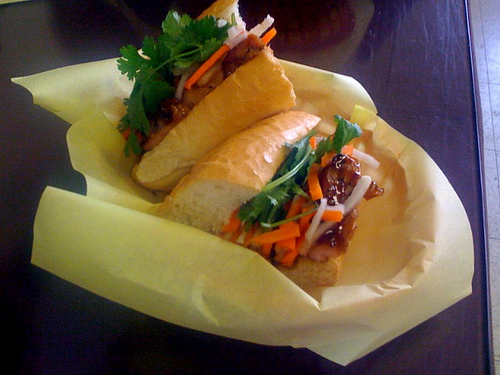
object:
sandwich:
[159, 109, 384, 285]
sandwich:
[117, 0, 297, 191]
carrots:
[257, 28, 276, 51]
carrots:
[256, 224, 297, 245]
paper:
[350, 104, 377, 132]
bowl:
[80, 65, 440, 319]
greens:
[332, 114, 361, 153]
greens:
[115, 44, 148, 82]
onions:
[299, 197, 328, 255]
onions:
[175, 70, 192, 98]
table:
[0, 2, 490, 372]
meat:
[317, 155, 385, 206]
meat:
[223, 35, 263, 75]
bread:
[155, 111, 320, 240]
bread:
[289, 252, 339, 290]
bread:
[134, 47, 300, 196]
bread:
[196, 0, 245, 27]